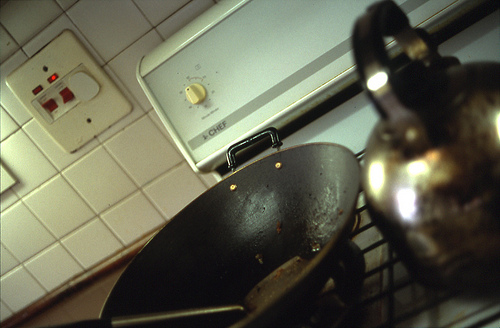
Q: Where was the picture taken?
A: In a kitchen.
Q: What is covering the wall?
A: Tile.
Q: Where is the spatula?
A: In wok.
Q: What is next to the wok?
A: A kettle.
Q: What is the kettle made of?
A: Metal.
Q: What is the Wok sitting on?
A: A stove.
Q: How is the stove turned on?
A: With knob.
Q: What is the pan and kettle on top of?
A: Stove.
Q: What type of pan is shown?
A: Wok.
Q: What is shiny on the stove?
A: Kettle.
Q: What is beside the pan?
A: Kettle.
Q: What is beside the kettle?
A: Pan.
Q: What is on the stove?
A: Pan and kettle.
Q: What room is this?
A: Kitchen.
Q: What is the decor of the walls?
A: Tile.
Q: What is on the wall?
A: Electrical switches.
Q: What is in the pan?
A: Spatula.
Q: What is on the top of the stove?
A: Knob.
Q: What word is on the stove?
A: Chef.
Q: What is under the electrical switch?
A: Counter.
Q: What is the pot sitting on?
A: Stove.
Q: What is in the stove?
A: Pan and kettle.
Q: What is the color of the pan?
A: Black.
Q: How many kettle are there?
A: 1.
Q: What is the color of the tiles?
A: White.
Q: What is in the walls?
A: Tiles.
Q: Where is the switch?
A: In the wall.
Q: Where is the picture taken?
A: On the stove.